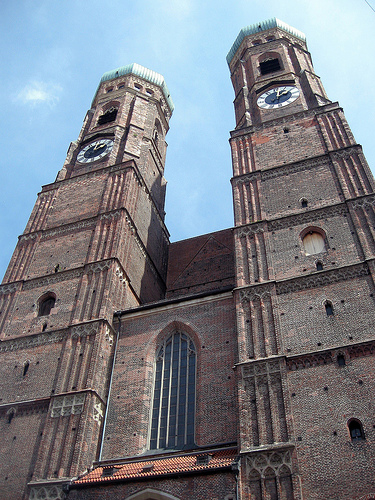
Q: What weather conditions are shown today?
A: It is clear.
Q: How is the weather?
A: It is clear.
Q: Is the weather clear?
A: Yes, it is clear.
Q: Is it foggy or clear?
A: It is clear.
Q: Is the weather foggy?
A: No, it is clear.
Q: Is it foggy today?
A: No, it is clear.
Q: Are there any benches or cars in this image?
A: No, there are no cars or benches.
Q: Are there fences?
A: No, there are no fences.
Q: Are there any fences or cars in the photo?
A: No, there are no fences or cars.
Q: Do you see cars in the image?
A: No, there are no cars.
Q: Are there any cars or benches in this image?
A: No, there are no cars or benches.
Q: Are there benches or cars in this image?
A: No, there are no cars or benches.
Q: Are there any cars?
A: No, there are no cars.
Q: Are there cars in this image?
A: No, there are no cars.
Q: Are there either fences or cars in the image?
A: No, there are no cars or fences.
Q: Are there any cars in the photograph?
A: No, there are no cars.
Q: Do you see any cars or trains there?
A: No, there are no cars or trains.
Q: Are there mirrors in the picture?
A: No, there are no mirrors.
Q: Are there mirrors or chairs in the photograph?
A: No, there are no mirrors or chairs.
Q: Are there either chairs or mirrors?
A: No, there are no mirrors or chairs.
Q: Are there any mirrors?
A: No, there are no mirrors.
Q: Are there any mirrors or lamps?
A: No, there are no mirrors or lamps.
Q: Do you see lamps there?
A: No, there are no lamps.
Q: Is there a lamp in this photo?
A: No, there are no lamps.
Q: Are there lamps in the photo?
A: No, there are no lamps.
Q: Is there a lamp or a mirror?
A: No, there are no lamps or mirrors.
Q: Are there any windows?
A: Yes, there is a window.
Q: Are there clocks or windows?
A: Yes, there is a window.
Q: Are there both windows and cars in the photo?
A: No, there is a window but no cars.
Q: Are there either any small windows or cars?
A: Yes, there is a small window.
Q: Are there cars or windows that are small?
A: Yes, the window is small.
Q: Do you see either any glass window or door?
A: Yes, there is a glass window.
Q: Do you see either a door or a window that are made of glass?
A: Yes, the window is made of glass.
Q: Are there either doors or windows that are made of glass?
A: Yes, the window is made of glass.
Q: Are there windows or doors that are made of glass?
A: Yes, the window is made of glass.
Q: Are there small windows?
A: Yes, there is a small window.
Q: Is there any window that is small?
A: Yes, there is a window that is small.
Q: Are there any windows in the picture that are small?
A: Yes, there is a window that is small.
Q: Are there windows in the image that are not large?
A: Yes, there is a small window.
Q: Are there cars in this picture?
A: No, there are no cars.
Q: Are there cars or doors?
A: No, there are no cars or doors.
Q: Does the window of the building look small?
A: Yes, the window is small.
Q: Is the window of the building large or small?
A: The window is small.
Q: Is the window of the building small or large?
A: The window is small.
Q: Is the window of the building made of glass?
A: Yes, the window is made of glass.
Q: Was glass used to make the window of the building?
A: Yes, the window is made of glass.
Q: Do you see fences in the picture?
A: No, there are no fences.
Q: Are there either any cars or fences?
A: No, there are no fences or cars.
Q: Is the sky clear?
A: Yes, the sky is clear.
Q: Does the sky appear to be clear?
A: Yes, the sky is clear.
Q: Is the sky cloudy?
A: No, the sky is clear.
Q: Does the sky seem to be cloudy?
A: No, the sky is clear.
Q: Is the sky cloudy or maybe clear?
A: The sky is clear.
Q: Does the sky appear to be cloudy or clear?
A: The sky is clear.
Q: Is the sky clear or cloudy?
A: The sky is clear.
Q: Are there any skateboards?
A: No, there are no skateboards.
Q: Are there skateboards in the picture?
A: No, there are no skateboards.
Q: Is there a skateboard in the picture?
A: No, there are no skateboards.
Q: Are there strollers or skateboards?
A: No, there are no skateboards or strollers.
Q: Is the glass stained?
A: Yes, the glass is stained.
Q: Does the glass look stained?
A: Yes, the glass is stained.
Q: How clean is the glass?
A: The glass is stained.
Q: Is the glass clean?
A: No, the glass is stained.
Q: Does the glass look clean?
A: No, the glass is stained.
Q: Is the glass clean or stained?
A: The glass is stained.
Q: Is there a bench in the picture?
A: No, there are no benches.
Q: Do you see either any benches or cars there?
A: No, there are no benches or cars.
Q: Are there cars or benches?
A: No, there are no benches or cars.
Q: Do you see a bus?
A: No, there are no buses.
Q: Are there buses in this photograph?
A: No, there are no buses.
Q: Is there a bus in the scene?
A: No, there are no buses.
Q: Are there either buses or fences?
A: No, there are no buses or fences.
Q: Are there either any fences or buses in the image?
A: No, there are no buses or fences.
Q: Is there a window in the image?
A: Yes, there is a window.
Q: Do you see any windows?
A: Yes, there is a window.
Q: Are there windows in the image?
A: Yes, there is a window.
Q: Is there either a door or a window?
A: Yes, there is a window.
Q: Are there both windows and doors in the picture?
A: No, there is a window but no doors.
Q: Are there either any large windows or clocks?
A: Yes, there is a large window.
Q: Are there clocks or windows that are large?
A: Yes, the window is large.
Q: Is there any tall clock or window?
A: Yes, there is a tall window.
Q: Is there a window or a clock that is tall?
A: Yes, the window is tall.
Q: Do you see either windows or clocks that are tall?
A: Yes, the window is tall.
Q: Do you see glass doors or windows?
A: Yes, there is a glass window.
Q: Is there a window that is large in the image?
A: Yes, there is a large window.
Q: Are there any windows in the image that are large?
A: Yes, there is a window that is large.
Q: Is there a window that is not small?
A: Yes, there is a large window.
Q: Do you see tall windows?
A: Yes, there is a tall window.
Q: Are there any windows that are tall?
A: Yes, there is a window that is tall.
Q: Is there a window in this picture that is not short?
A: Yes, there is a tall window.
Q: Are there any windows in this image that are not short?
A: Yes, there is a tall window.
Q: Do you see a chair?
A: No, there are no chairs.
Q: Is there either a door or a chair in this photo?
A: No, there are no chairs or doors.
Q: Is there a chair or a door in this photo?
A: No, there are no chairs or doors.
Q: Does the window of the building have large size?
A: Yes, the window is large.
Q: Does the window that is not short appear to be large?
A: Yes, the window is large.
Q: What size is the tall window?
A: The window is large.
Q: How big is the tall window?
A: The window is large.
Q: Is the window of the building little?
A: No, the window is large.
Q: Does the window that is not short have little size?
A: No, the window is large.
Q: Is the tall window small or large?
A: The window is large.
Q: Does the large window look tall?
A: Yes, the window is tall.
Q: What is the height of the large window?
A: The window is tall.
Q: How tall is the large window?
A: The window is tall.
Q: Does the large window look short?
A: No, the window is tall.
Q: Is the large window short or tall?
A: The window is tall.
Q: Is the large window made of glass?
A: Yes, the window is made of glass.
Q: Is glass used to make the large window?
A: Yes, the window is made of glass.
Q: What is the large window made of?
A: The window is made of glass.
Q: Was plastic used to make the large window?
A: No, the window is made of glass.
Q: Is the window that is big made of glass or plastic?
A: The window is made of glass.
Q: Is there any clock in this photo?
A: Yes, there is a clock.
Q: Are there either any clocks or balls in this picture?
A: Yes, there is a clock.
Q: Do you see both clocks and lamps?
A: No, there is a clock but no lamps.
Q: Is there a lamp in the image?
A: No, there are no lamps.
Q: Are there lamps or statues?
A: No, there are no lamps or statues.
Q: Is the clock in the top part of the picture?
A: Yes, the clock is in the top of the image.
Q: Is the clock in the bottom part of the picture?
A: No, the clock is in the top of the image.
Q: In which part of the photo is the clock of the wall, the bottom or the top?
A: The clock is in the top of the image.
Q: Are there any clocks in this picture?
A: Yes, there is a clock.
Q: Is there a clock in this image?
A: Yes, there is a clock.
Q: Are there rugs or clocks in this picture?
A: Yes, there is a clock.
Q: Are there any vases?
A: No, there are no vases.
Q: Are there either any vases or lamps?
A: No, there are no vases or lamps.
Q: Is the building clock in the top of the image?
A: Yes, the clock is in the top of the image.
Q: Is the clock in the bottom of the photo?
A: No, the clock is in the top of the image.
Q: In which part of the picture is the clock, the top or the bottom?
A: The clock is in the top of the image.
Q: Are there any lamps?
A: No, there are no lamps.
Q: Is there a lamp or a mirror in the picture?
A: No, there are no lamps or mirrors.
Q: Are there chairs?
A: No, there are no chairs.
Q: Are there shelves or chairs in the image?
A: No, there are no chairs or shelves.